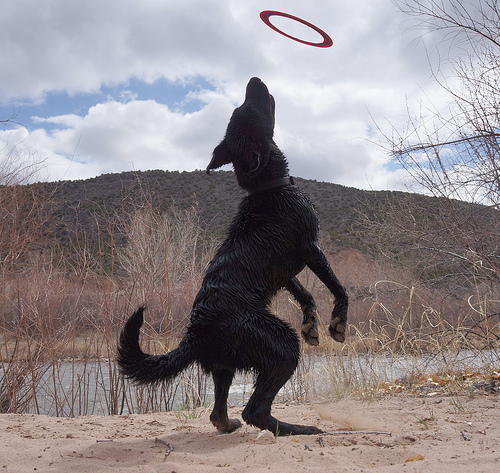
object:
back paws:
[214, 417, 242, 434]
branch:
[114, 184, 140, 213]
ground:
[0, 350, 500, 473]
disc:
[259, 9, 332, 48]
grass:
[317, 326, 497, 389]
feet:
[273, 423, 323, 436]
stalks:
[2, 278, 45, 398]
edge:
[3, 367, 498, 416]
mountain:
[4, 170, 360, 323]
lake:
[2, 347, 498, 417]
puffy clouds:
[4, 119, 74, 183]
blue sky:
[0, 0, 500, 206]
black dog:
[112, 78, 351, 438]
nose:
[247, 77, 262, 88]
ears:
[205, 140, 232, 177]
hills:
[353, 180, 496, 296]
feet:
[300, 320, 323, 348]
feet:
[325, 317, 349, 344]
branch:
[355, 94, 498, 196]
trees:
[2, 154, 73, 414]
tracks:
[7, 421, 61, 446]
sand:
[3, 386, 498, 471]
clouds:
[0, 3, 500, 97]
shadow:
[56, 427, 272, 471]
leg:
[205, 363, 238, 424]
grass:
[0, 213, 495, 421]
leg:
[238, 311, 299, 430]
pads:
[309, 328, 320, 339]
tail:
[112, 301, 188, 383]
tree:
[373, 0, 500, 237]